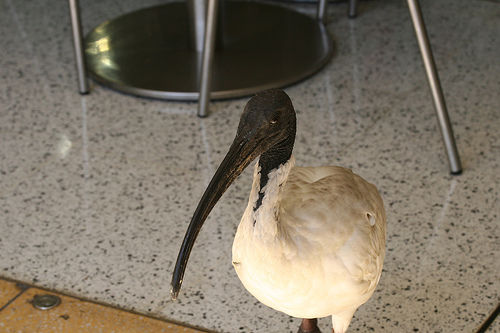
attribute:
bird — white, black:
[168, 87, 388, 332]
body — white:
[230, 162, 388, 318]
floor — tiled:
[0, 0, 499, 331]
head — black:
[169, 89, 297, 300]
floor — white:
[20, 105, 149, 263]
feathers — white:
[303, 202, 364, 263]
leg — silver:
[398, 0, 463, 177]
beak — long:
[157, 139, 257, 290]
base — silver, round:
[68, 2, 348, 110]